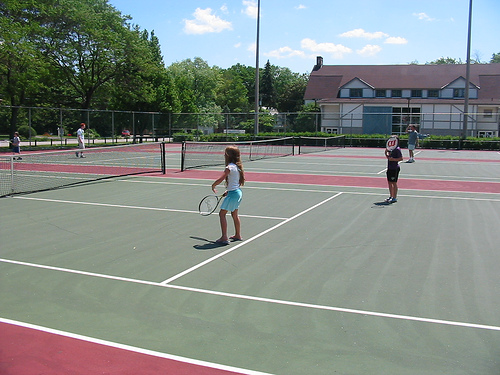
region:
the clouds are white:
[284, 33, 386, 70]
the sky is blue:
[289, 16, 415, 69]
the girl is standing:
[193, 126, 259, 259]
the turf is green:
[298, 238, 391, 301]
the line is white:
[235, 274, 432, 351]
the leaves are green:
[45, 16, 140, 83]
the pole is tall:
[235, 4, 292, 149]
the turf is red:
[22, 346, 62, 370]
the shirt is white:
[220, 165, 250, 186]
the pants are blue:
[218, 192, 250, 219]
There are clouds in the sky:
[2, 0, 488, 339]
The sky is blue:
[110, 0, 495, 153]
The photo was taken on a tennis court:
[18, 9, 476, 358]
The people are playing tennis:
[18, 72, 482, 372]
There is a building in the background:
[74, 20, 486, 167]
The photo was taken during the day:
[27, 11, 484, 351]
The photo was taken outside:
[33, 43, 453, 330]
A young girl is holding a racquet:
[151, 104, 311, 326]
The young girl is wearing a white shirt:
[188, 119, 305, 318]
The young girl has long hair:
[126, 114, 354, 292]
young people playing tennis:
[208, 131, 435, 244]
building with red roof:
[291, 44, 499, 142]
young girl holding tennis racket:
[179, 145, 252, 249]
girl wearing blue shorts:
[213, 186, 250, 220]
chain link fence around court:
[15, 95, 493, 149]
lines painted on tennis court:
[2, 241, 494, 343]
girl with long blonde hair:
[216, 142, 258, 192]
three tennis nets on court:
[11, 126, 366, 181]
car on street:
[106, 122, 148, 143]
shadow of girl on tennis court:
[173, 231, 235, 261]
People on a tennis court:
[40, 90, 466, 298]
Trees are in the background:
[18, 9, 353, 240]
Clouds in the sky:
[155, 0, 475, 142]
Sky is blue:
[179, 12, 493, 129]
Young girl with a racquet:
[165, 145, 347, 320]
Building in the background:
[293, 22, 488, 221]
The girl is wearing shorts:
[158, 112, 296, 272]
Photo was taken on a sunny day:
[35, 9, 477, 310]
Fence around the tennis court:
[31, 22, 445, 288]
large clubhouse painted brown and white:
[215, 51, 483, 142]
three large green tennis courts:
[155, 208, 457, 341]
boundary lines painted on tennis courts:
[6, 202, 476, 318]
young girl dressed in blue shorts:
[172, 130, 276, 276]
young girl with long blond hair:
[172, 155, 287, 253]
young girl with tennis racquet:
[180, 144, 277, 279]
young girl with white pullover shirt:
[188, 142, 268, 211]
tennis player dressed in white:
[52, 124, 99, 181]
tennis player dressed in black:
[360, 111, 416, 226]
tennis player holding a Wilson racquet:
[364, 129, 430, 219]